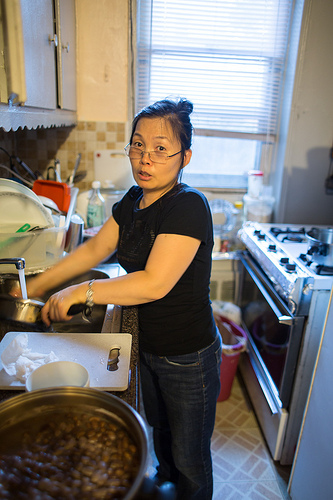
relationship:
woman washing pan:
[18, 99, 225, 499] [4, 299, 87, 328]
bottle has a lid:
[243, 169, 265, 198] [247, 169, 264, 178]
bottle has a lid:
[241, 196, 275, 223] [233, 200, 244, 209]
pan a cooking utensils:
[6, 297, 93, 327] [0, 155, 80, 258]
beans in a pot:
[48, 416, 107, 459] [0, 384, 153, 500]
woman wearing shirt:
[18, 99, 225, 499] [113, 187, 220, 353]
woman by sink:
[18, 99, 225, 499] [2, 250, 126, 348]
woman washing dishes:
[125, 96, 196, 200] [2, 178, 61, 233]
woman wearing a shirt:
[18, 99, 225, 499] [113, 187, 220, 353]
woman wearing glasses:
[18, 99, 225, 499] [123, 141, 186, 162]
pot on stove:
[300, 224, 331, 269] [234, 221, 323, 463]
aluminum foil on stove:
[236, 226, 307, 309] [236, 220, 332, 467]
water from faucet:
[18, 278, 36, 294] [1, 230, 31, 286]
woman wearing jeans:
[100, 95, 206, 297] [135, 329, 222, 498]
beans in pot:
[0, 413, 136, 495] [0, 387, 177, 499]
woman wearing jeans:
[109, 112, 216, 327] [152, 317, 222, 444]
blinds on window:
[133, 0, 308, 142] [134, 1, 296, 194]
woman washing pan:
[18, 99, 225, 499] [1, 288, 48, 327]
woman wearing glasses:
[62, 91, 265, 484] [124, 140, 186, 161]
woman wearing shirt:
[18, 99, 225, 499] [108, 181, 216, 357]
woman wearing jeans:
[18, 99, 225, 499] [133, 339, 226, 498]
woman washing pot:
[18, 99, 225, 499] [0, 291, 93, 326]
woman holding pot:
[44, 92, 227, 379] [14, 269, 110, 349]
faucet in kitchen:
[2, 259, 31, 311] [6, 4, 322, 495]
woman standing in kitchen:
[51, 82, 230, 495] [51, 5, 333, 492]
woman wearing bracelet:
[122, 103, 223, 409] [82, 280, 93, 310]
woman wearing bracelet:
[18, 99, 225, 499] [69, 274, 103, 314]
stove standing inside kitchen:
[242, 216, 330, 302] [6, 4, 322, 495]